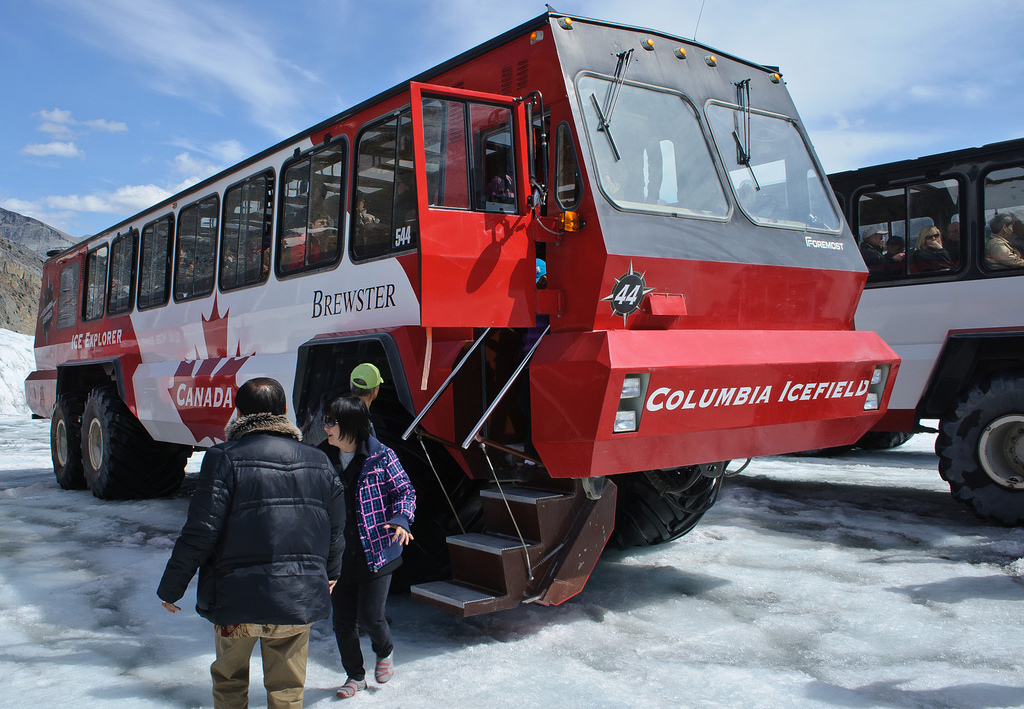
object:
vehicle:
[24, 5, 903, 618]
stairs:
[410, 472, 616, 617]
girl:
[320, 397, 418, 699]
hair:
[321, 397, 368, 446]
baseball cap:
[351, 363, 386, 390]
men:
[156, 377, 347, 709]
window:
[348, 96, 449, 265]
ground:
[0, 329, 1022, 709]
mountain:
[0, 208, 95, 336]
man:
[350, 363, 385, 410]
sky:
[0, 0, 1024, 238]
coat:
[154, 412, 346, 627]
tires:
[80, 383, 193, 501]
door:
[410, 81, 538, 328]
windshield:
[573, 69, 844, 235]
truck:
[826, 139, 1024, 529]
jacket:
[321, 433, 417, 573]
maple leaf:
[167, 289, 255, 445]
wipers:
[591, 48, 637, 163]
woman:
[913, 225, 957, 272]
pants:
[210, 622, 309, 709]